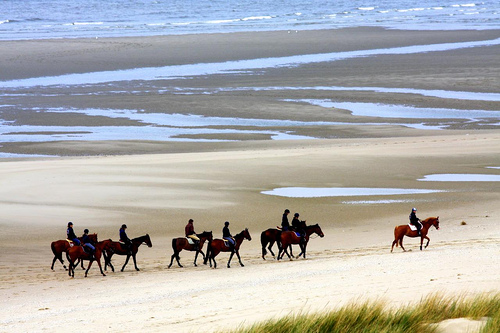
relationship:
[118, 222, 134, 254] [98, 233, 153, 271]
person riding horse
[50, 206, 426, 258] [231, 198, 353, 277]
people riding horses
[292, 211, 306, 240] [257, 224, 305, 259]
person on horse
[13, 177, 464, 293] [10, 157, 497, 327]
horses on beach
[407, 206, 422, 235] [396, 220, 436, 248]
people riding horse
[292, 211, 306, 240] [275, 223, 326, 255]
person riding horse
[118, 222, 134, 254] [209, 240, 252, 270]
person riding horse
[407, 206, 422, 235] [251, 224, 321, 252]
people riding horse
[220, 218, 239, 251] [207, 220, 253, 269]
person riding horse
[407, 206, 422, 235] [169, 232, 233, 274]
people riding horse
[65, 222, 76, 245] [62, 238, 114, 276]
person riding horse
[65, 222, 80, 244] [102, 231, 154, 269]
person riding horse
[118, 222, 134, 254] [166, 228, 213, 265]
person riding horse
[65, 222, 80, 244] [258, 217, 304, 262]
person riding horse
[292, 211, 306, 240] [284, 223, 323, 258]
person riding horse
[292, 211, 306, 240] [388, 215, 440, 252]
person riding horse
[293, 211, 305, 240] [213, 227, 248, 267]
person riding horse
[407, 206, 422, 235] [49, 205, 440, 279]
people on horses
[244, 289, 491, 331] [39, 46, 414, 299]
grass on beach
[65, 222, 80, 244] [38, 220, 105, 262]
person on horse